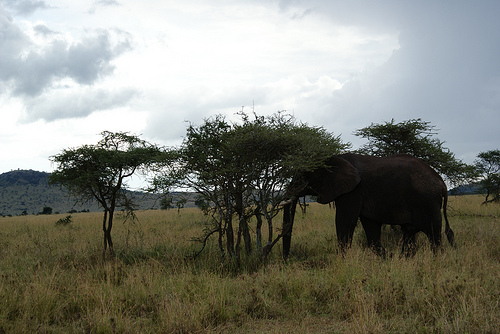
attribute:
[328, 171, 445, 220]
elephant — brown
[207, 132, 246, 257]
tree — bushy, green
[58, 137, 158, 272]
tree — short, green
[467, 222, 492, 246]
grass — tall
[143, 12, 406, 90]
sky — cloudy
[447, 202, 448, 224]
tail — long, thin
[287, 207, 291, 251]
trunk — long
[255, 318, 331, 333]
ground — flat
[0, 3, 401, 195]
bad clouds — grey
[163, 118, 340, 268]
tree — small, green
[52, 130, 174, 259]
tree — small, green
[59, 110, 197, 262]
tree — tiny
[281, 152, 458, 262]
elephant — grey, tall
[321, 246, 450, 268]
grass — tall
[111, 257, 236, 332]
grass — light green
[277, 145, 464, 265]
elephant — black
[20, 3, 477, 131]
sky — cloudy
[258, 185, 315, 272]
trunk — long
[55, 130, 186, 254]
tree — large, green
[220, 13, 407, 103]
clouds — fluffy, white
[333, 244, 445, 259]
feet — large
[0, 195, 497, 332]
grass — dry-looking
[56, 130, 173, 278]
tree — green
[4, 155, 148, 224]
large hill — distant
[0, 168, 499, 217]
mountain — small, distant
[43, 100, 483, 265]
bushes — thorn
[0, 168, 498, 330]
grass — sparse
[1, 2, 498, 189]
clouds — dark, grey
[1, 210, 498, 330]
grass — brown, green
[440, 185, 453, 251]
tail — long, thin